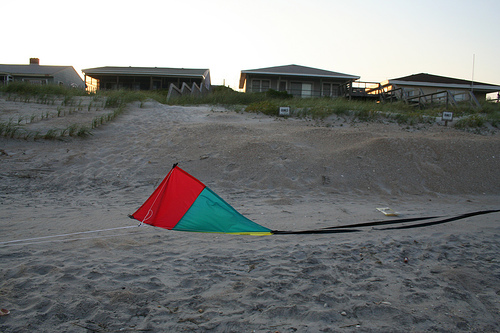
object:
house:
[0, 57, 88, 97]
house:
[80, 65, 212, 104]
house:
[238, 63, 362, 102]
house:
[364, 71, 500, 107]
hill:
[1, 95, 500, 193]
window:
[301, 82, 312, 98]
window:
[252, 80, 260, 92]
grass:
[0, 82, 499, 142]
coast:
[0, 95, 498, 201]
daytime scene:
[0, 0, 500, 333]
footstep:
[37, 265, 53, 276]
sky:
[0, 0, 500, 83]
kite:
[125, 161, 500, 236]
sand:
[0, 101, 500, 333]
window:
[322, 82, 331, 96]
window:
[139, 76, 151, 90]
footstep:
[405, 292, 431, 304]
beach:
[0, 197, 499, 332]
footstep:
[352, 303, 417, 330]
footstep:
[228, 280, 248, 294]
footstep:
[127, 286, 150, 295]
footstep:
[295, 256, 323, 269]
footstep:
[84, 271, 106, 281]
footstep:
[315, 274, 338, 287]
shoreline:
[0, 191, 500, 207]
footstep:
[113, 273, 146, 283]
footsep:
[405, 291, 431, 305]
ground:
[0, 95, 495, 333]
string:
[0, 225, 139, 245]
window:
[278, 80, 286, 91]